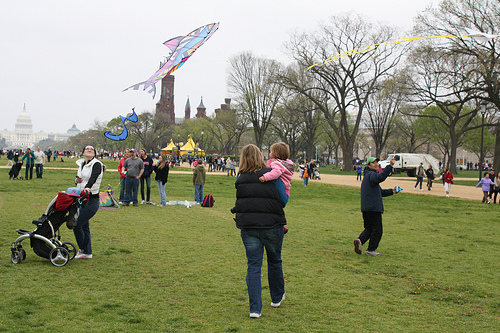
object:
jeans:
[239, 226, 289, 313]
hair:
[271, 142, 288, 160]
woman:
[232, 142, 293, 317]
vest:
[228, 168, 289, 231]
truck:
[377, 150, 444, 172]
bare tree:
[268, 21, 405, 172]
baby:
[258, 141, 295, 238]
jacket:
[260, 156, 298, 197]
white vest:
[73, 158, 108, 196]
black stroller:
[10, 186, 94, 272]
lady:
[71, 143, 107, 260]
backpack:
[200, 194, 217, 209]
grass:
[0, 166, 500, 332]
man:
[352, 156, 400, 258]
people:
[192, 158, 205, 206]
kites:
[102, 21, 222, 143]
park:
[2, 138, 500, 332]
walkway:
[288, 168, 500, 205]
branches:
[344, 67, 369, 91]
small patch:
[154, 279, 174, 289]